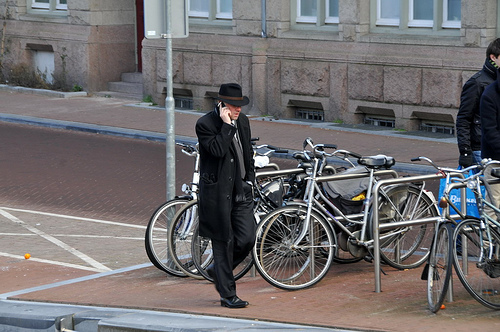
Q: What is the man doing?
A: Talking on the phone.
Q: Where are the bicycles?
A: Parked on the street.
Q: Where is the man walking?
A: Next to the bicycles.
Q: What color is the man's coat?
A: Black.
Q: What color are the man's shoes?
A: Black.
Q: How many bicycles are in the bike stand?
A: 6.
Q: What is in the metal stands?
A: Bikes.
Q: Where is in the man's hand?
A: Cellphone.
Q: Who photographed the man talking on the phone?
A: An amateur photographer.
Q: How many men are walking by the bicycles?
A: 2.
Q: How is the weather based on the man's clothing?
A: Cold.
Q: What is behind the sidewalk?
A: An apartment building.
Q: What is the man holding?
A: A cell phone.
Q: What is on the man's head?
A: A hat.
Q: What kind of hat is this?
A: A fedora.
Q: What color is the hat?
A: Black and brown.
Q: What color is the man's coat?
A: Black.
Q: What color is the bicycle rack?
A: Silver.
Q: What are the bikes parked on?
A: The sidewalk.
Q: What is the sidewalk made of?
A: Brick.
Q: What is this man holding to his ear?
A: Phone.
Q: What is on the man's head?
A: Hat.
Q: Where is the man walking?
A: Sidewalk.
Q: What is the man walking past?
A: Bicycles.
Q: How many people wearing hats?
A: One.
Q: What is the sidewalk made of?
A: Bricks.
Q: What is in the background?
A: Buildings.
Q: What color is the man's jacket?
A: Black.